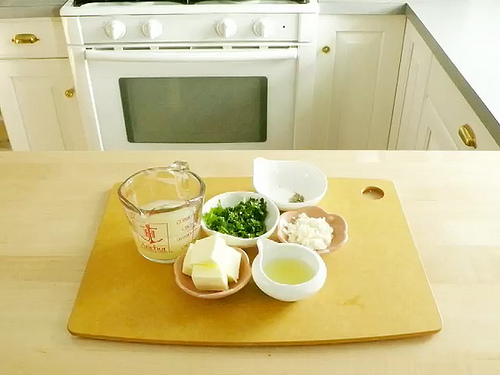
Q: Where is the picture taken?
A: A kitchen.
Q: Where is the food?
A: On cutting board.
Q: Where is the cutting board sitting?
A: The counter.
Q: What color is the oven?
A: White.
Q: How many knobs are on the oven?
A: 4.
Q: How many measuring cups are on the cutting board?
A: One.